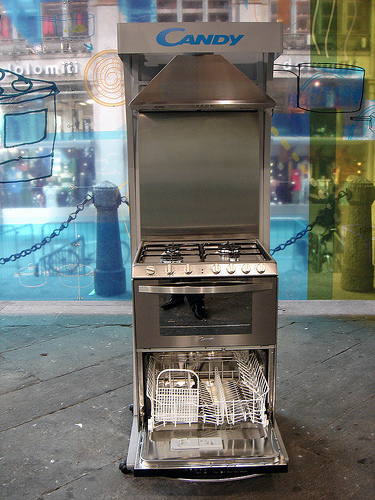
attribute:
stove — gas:
[137, 236, 279, 285]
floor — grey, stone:
[7, 303, 371, 499]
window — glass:
[156, 284, 251, 335]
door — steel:
[131, 280, 277, 348]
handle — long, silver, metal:
[139, 287, 279, 297]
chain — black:
[2, 188, 350, 260]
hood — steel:
[131, 49, 274, 237]